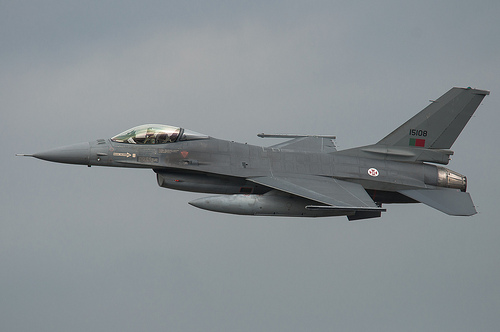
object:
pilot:
[142, 125, 156, 145]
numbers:
[409, 129, 428, 137]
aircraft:
[19, 82, 489, 222]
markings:
[408, 128, 428, 147]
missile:
[188, 182, 364, 218]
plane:
[14, 84, 491, 221]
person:
[143, 127, 156, 144]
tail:
[375, 85, 491, 164]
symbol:
[367, 167, 380, 177]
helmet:
[145, 125, 155, 134]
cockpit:
[112, 123, 209, 144]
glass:
[110, 123, 181, 145]